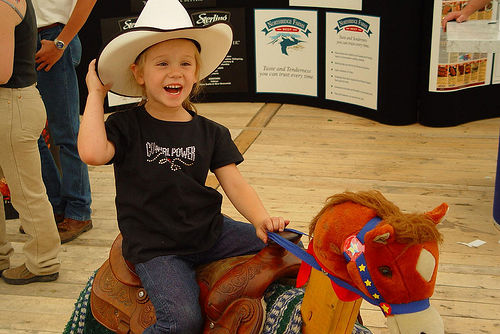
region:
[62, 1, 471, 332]
a boy riding a ride on pony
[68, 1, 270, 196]
a smiling boy holding his hat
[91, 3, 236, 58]
a cowboy hat the boy is wearing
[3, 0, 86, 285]
a group of people standing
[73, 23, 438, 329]
a boy in jeans riding a toy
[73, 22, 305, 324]
a boy in black shirt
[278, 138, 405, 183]
a hardwood floor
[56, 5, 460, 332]
a happy boy riding a ride-on horse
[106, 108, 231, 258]
black shirt the boy is wearing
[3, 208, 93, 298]
shoes the people in the background is wearing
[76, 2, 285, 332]
young child dressed as cowboy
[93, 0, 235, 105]
a white cowboy hat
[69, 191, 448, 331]
a toy horse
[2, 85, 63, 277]
a woman's tan pants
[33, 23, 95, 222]
a pair of blue jeans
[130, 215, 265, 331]
a pair of child's blue jeans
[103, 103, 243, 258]
a black printed t-shirt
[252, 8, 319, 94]
a white promotional sign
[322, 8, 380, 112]
a white promotional sign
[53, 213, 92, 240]
a brown shoe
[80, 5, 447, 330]
A child sitting on a toy horse.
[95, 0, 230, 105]
The child is wearing a cowboy hat.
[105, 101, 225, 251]
A child wearing a black shirt with lettering on the front.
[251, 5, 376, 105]
Paper signs hanging on the wall.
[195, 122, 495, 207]
A wooden floor.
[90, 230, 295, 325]
A saddle on the toy horse's back.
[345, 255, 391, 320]
yellow stars on the toy horse's reins.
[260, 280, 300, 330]
A patterned blanket beneath the saddle.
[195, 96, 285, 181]
A brown stripe on the wooden floor.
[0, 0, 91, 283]
People standing together.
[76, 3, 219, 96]
white and black cowboy hat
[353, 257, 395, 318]
four yellow stars on horse bridle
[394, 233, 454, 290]
white diamond on horses head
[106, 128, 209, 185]
writing that says cowgirl power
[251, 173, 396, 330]
green and white blanket under horse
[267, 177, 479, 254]
tan mane of a horse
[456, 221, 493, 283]
white piece of garbage on floor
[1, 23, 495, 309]
girl riding a fake horse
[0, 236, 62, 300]
brown and black loafers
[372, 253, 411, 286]
glass eye of a horse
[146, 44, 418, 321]
A young girl on a stuffed pony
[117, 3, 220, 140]
Young girl wearing a cowboy hat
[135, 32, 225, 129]
Girl in a hat is happy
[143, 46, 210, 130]
Girl is smiling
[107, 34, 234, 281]
Little girl is wearing a black shirt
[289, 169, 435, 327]
A stuffed pony for a child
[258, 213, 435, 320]
Pony has a blue bridle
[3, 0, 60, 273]
A woman wearing tan pants and a black shirt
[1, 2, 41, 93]
Black shirt is sleeveless on one side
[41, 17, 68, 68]
Wristwatch on a mans wrist